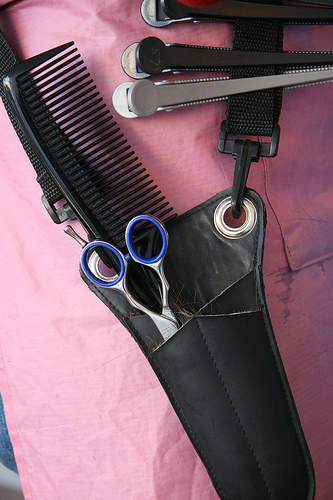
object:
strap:
[213, 5, 295, 140]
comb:
[0, 38, 183, 322]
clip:
[218, 120, 279, 214]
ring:
[209, 195, 260, 243]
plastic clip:
[217, 121, 279, 217]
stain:
[272, 266, 304, 317]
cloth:
[269, 151, 330, 339]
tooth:
[15, 35, 168, 250]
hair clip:
[138, 0, 331, 30]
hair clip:
[118, 34, 332, 80]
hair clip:
[109, 63, 330, 120]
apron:
[0, 0, 332, 499]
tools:
[139, 0, 333, 30]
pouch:
[0, 0, 332, 498]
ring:
[127, 216, 166, 263]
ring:
[79, 240, 125, 286]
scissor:
[63, 213, 179, 343]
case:
[78, 185, 320, 498]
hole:
[207, 189, 259, 242]